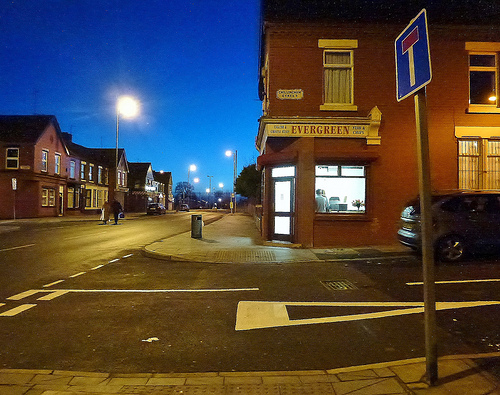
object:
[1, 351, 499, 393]
sidewalk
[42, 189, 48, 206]
window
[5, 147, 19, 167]
window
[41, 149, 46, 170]
window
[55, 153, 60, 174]
window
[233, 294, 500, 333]
lines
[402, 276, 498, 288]
lines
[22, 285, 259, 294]
lines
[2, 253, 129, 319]
lines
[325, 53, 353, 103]
window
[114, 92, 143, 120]
lamp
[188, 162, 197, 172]
lamp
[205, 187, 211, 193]
lamp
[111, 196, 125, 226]
person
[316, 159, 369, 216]
window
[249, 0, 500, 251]
building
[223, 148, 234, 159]
lamp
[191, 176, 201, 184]
lamp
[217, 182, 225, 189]
lamp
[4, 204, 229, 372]
street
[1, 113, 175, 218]
buildings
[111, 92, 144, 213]
street light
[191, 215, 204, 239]
garbage can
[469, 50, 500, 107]
window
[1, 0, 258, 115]
blue sky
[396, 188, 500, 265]
car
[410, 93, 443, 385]
pole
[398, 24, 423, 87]
t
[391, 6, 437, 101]
sign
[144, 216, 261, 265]
sidewalk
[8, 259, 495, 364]
street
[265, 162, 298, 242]
door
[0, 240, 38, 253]
lines